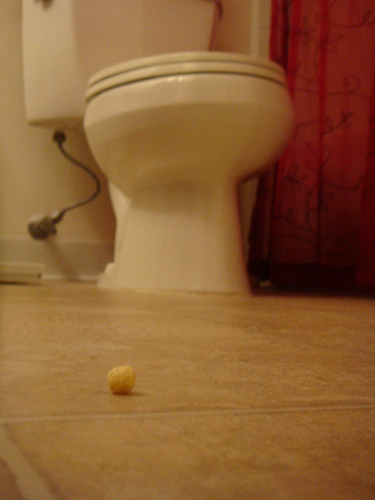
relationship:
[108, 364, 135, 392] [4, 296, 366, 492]
cereal resting on floor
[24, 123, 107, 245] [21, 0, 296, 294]
pipe connected to toilet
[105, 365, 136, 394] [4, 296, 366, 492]
food on floor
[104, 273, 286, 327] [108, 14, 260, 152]
caulking around base of a toilet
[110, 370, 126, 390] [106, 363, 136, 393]
piece of cereal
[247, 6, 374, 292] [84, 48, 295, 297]
curtain beside a toiletseat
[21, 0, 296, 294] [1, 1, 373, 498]
toilet in a bathroom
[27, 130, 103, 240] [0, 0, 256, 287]
pipe on wall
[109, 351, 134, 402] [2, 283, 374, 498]
ball on floor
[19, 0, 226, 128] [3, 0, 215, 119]
toilet tank of toilet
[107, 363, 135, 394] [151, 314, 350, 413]
ball on floor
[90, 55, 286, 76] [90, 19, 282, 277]
lid on toilet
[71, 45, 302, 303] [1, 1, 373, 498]
toilet in bathroom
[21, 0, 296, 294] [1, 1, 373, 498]
toilet in bathroom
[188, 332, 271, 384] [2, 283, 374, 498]
part of floor